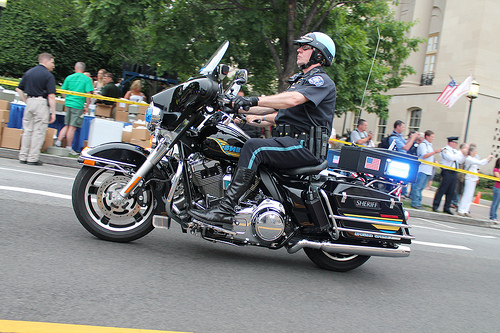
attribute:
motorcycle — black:
[68, 27, 416, 275]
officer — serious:
[183, 27, 343, 231]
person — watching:
[410, 129, 448, 216]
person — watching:
[378, 117, 420, 201]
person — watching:
[343, 117, 376, 149]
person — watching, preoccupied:
[461, 141, 496, 221]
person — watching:
[7, 43, 62, 170]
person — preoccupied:
[58, 48, 100, 160]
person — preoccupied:
[94, 71, 122, 111]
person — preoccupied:
[90, 64, 107, 88]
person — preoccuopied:
[121, 75, 152, 104]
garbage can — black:
[334, 140, 391, 181]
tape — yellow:
[1, 77, 500, 201]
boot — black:
[183, 164, 260, 234]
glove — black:
[224, 89, 262, 115]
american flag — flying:
[433, 77, 460, 112]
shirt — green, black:
[57, 70, 96, 112]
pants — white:
[454, 175, 480, 218]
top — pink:
[489, 163, 500, 190]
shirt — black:
[12, 61, 60, 99]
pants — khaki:
[13, 94, 55, 169]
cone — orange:
[469, 185, 488, 208]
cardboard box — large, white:
[82, 113, 129, 149]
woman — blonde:
[122, 74, 150, 105]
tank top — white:
[126, 91, 146, 102]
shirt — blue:
[381, 130, 410, 160]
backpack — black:
[376, 133, 403, 150]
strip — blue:
[246, 135, 311, 173]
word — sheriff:
[349, 195, 387, 213]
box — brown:
[1, 123, 25, 156]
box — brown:
[45, 124, 60, 152]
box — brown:
[1, 106, 10, 122]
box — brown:
[93, 102, 115, 119]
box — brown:
[0, 96, 12, 109]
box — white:
[84, 114, 129, 152]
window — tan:
[416, 28, 444, 92]